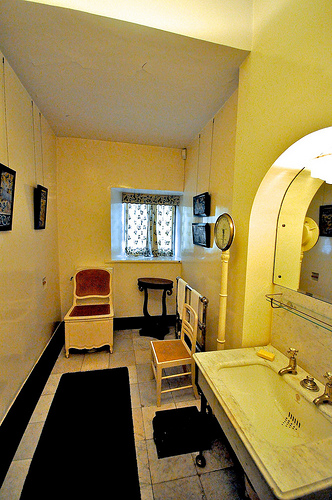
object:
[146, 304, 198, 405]
chair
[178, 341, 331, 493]
sink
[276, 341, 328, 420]
faucet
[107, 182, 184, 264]
window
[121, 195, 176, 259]
curtain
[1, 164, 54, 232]
picture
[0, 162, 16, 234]
frame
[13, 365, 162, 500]
rug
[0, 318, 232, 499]
floor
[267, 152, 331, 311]
mirror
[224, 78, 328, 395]
wall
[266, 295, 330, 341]
shelf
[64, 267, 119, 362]
chair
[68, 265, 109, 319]
cushions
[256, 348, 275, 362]
soap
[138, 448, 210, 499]
tile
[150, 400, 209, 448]
scale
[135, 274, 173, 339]
table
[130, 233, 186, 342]
corner